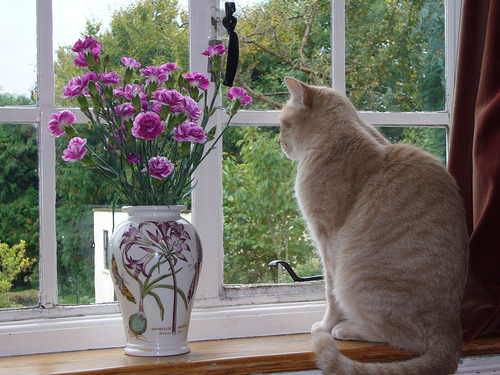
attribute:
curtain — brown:
[454, 0, 496, 369]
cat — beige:
[250, 68, 484, 373]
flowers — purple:
[67, 43, 205, 183]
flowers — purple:
[51, 40, 253, 209]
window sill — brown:
[198, 333, 313, 367]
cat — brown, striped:
[274, 71, 468, 366]